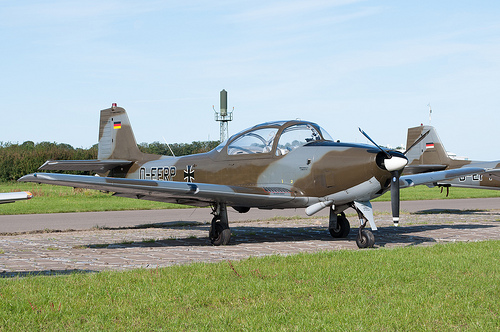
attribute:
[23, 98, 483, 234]
jet — vintage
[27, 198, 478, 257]
runway — concrete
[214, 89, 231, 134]
tower — gray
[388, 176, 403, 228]
propeller — black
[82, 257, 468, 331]
grass — short, green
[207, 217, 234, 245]
wheel — black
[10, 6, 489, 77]
sky — blue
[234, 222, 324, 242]
shadow — black